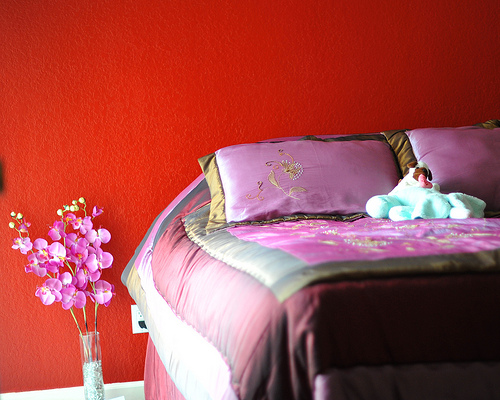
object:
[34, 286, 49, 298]
flower pedal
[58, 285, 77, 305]
flower pedal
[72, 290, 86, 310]
flower pedal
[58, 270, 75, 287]
flower pedal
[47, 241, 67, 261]
flower pedal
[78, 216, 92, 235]
flower pedal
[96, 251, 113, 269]
flower pedal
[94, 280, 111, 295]
flower pedal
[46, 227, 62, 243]
flower pedal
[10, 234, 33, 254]
flower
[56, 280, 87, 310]
flower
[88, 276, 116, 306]
flower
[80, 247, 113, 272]
flower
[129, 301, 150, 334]
electrical outlet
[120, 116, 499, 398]
bed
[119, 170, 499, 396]
blanket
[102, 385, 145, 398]
floor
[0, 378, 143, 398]
wainscoting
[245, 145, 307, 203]
decoration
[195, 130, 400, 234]
pillow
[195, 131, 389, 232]
border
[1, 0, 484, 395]
room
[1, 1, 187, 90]
wall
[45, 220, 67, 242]
flower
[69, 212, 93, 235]
flower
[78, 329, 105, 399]
vase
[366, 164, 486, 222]
toy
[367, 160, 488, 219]
bear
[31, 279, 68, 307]
flower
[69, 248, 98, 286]
flower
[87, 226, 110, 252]
flower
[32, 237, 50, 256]
flower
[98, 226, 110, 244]
petal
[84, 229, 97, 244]
petal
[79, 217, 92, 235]
petal